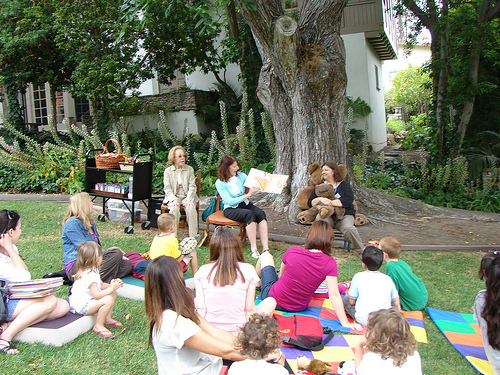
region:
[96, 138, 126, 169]
Brown basket with a handle.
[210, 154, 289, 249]
Lady in blue sweater telling a story.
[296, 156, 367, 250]
Lady holding a teddy bear.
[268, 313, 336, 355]
Red messenger bag or backpack.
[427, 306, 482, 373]
Multi colored lawn quilt.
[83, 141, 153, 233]
Black cart with wheels.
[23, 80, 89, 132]
Window with many panes.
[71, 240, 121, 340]
Little girl listening to story.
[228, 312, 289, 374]
Child with curly hair.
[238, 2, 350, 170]
Very large tree trunk.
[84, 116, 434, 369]
people that are sitting outside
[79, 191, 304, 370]
adults that are sitting outside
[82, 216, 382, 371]
children sitting outside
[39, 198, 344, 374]
children sitting on the ground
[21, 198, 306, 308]
adults sittin gon the ground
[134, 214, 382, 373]
children sitting on mats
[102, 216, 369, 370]
children sitting on grass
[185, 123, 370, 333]
a lady reading a book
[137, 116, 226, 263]
a woman sitting on chair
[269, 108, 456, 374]
woman sitting under tree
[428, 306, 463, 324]
blue square on patchwork quilt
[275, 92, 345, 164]
large brown tree trunk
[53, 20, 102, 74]
green leaves on trees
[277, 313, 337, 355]
red and black backpack in middle of quilt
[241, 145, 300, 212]
story book being read by lady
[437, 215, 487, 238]
brown dirt in front of tree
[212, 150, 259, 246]
woman reading aloud a story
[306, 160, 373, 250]
giant brown bear behind woman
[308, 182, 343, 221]
little brown bear in woman's arms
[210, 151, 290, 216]
woman holding a book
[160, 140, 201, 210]
woman sitting on a chair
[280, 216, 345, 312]
girl sitting on mat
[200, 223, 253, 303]
girl sitting on mat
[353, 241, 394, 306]
boy sittting on a mat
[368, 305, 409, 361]
girl sitting on mat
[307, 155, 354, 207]
woman sitting next to tree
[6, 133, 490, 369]
several parents and their children at story-time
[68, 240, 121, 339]
a young girl with blonde hair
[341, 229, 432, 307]
two young boys listening to a story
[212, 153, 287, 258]
a woman reading a story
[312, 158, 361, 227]
a woman holding a teddy bear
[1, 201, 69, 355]
a woman with black hair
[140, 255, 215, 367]
a woman with brown hair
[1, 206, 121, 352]
a woman and her daughter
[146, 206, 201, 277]
a boy with blonde hair and a yellow shirt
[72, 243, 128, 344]
child listening to story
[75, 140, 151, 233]
A black cart on wheels.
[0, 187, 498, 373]
People sitting on blankets on the ground.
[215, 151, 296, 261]
A woman holding open a book.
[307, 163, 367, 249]
A woman with her arms wrapped around a teddy bear.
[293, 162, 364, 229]
A large teddy bear resting against the tree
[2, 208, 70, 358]
A person with books stacked on her lap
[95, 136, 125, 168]
A brown woven basket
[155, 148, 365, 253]
Women sitting in chairs.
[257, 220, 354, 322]
A woman with brown hair.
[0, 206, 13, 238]
A pair of sunglasses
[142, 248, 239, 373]
A woman with brown hair.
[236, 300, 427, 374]
Children with curly hair.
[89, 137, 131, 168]
A basket on a cart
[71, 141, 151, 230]
A black cart.